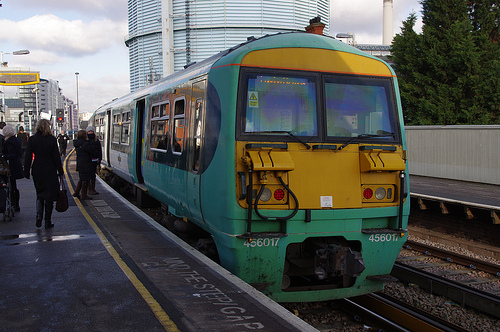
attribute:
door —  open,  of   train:
[129, 93, 152, 189]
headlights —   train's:
[249, 187, 286, 205]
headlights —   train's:
[360, 184, 392, 200]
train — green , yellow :
[171, 47, 416, 317]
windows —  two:
[144, 99, 186, 154]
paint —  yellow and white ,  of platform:
[136, 240, 276, 328]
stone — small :
[428, 294, 456, 316]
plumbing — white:
[394, 250, 498, 308]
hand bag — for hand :
[55, 173, 69, 210]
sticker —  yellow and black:
[243, 89, 258, 106]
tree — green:
[418, 10, 483, 123]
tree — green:
[466, 9, 498, 121]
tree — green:
[387, 12, 436, 129]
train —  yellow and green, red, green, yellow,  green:
[79, 6, 417, 312]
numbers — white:
[364, 232, 433, 254]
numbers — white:
[239, 227, 324, 253]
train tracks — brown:
[289, 222, 467, 328]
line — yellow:
[56, 138, 181, 330]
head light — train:
[357, 170, 410, 212]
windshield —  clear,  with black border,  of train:
[228, 64, 407, 161]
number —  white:
[365, 231, 396, 243]